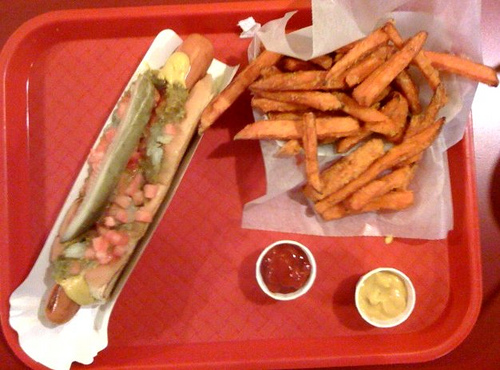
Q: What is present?
A: Food.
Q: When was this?
A: Daytime.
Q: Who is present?
A: Nobody.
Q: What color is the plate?
A: Red.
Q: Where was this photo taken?
A: At a fast food restaurant.